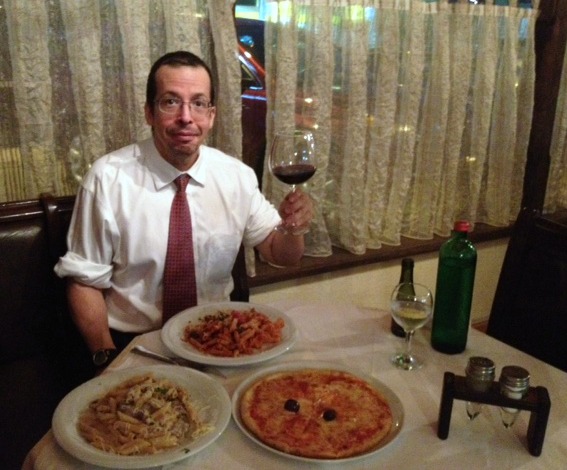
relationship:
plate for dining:
[228, 352, 411, 463] [34, 32, 440, 467]